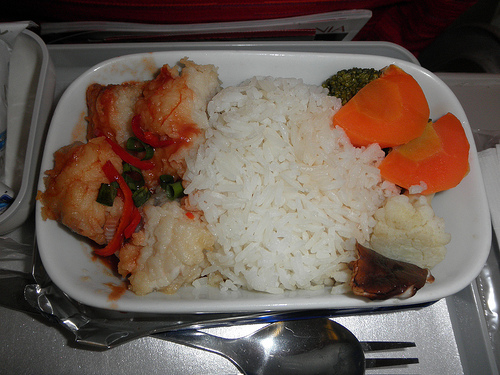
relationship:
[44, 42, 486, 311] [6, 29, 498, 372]
plate on tray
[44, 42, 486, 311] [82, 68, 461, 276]
plate of food